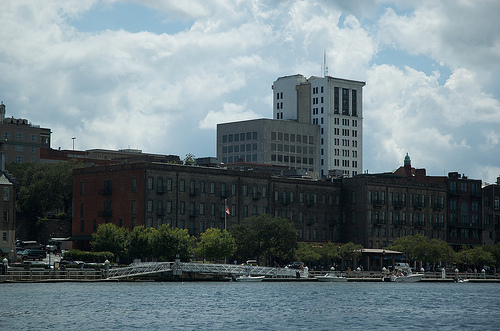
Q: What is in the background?
A: Tall buildings.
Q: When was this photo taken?
A: During the day.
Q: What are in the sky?
A: Clouds.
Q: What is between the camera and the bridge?
A: Water.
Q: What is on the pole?
A: A flag.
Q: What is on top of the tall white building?
A: A tower.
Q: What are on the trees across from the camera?
A: Leaves.